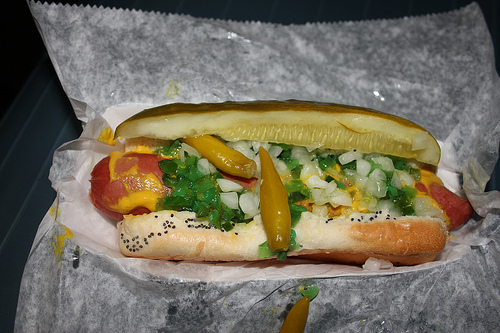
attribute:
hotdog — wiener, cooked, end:
[90, 148, 475, 232]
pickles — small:
[182, 136, 294, 254]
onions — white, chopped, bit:
[308, 175, 352, 208]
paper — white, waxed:
[14, 1, 499, 330]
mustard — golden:
[52, 130, 158, 255]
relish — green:
[168, 157, 241, 213]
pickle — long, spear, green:
[115, 100, 440, 169]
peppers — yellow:
[180, 134, 295, 254]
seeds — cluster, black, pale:
[114, 214, 186, 254]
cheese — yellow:
[116, 190, 156, 211]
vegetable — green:
[286, 157, 308, 206]